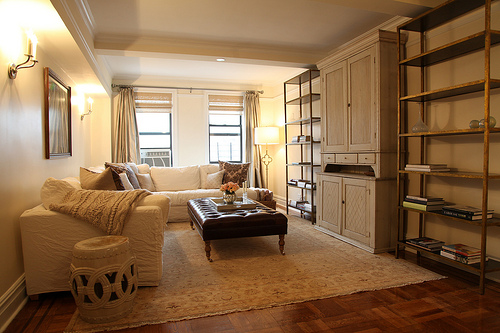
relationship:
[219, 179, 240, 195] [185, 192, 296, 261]
flowers are on ottoman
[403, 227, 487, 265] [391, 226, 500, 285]
books are on bottom shelf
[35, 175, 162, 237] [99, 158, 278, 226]
blanket on couch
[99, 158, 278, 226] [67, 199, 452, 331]
couch on rug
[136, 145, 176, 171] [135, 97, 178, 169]
air conditioner in window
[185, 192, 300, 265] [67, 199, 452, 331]
ottoman on rug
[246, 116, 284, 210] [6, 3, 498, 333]
floor lamp in living room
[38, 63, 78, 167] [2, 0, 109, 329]
art on wall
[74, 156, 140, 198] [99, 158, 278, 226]
pillows are on couch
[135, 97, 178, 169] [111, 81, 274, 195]
window with curtains